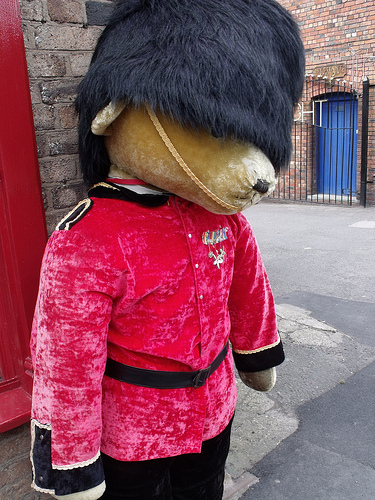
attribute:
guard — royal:
[27, 0, 303, 498]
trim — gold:
[231, 330, 281, 353]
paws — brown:
[237, 349, 283, 387]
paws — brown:
[34, 458, 114, 499]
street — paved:
[268, 209, 367, 300]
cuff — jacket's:
[46, 170, 283, 499]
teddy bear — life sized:
[67, 32, 244, 485]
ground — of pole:
[310, 97, 330, 120]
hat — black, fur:
[75, 0, 306, 186]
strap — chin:
[143, 100, 243, 211]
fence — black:
[295, 82, 373, 193]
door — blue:
[304, 88, 367, 203]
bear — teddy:
[48, 13, 373, 471]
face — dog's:
[109, 96, 278, 218]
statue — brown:
[20, 2, 304, 492]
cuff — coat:
[87, 216, 286, 370]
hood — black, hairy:
[55, 6, 346, 164]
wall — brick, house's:
[245, 1, 373, 208]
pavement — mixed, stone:
[249, 224, 374, 372]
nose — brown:
[254, 177, 269, 193]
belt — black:
[100, 344, 233, 390]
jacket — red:
[33, 179, 285, 499]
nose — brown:
[254, 181, 271, 195]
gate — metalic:
[290, 74, 369, 211]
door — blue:
[319, 96, 356, 194]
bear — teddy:
[22, 0, 308, 499]